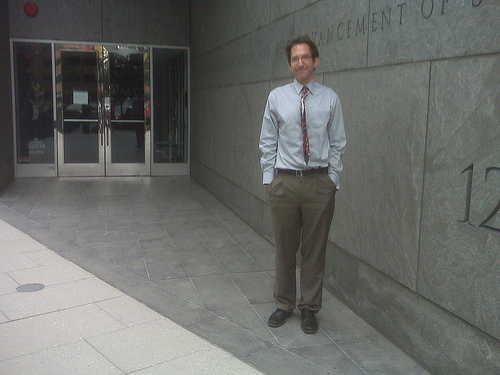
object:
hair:
[285, 34, 319, 67]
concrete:
[1, 174, 433, 375]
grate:
[16, 283, 45, 293]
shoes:
[267, 307, 294, 328]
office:
[9, 38, 190, 183]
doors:
[11, 40, 56, 179]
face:
[290, 43, 315, 81]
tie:
[300, 86, 310, 164]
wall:
[193, 0, 500, 375]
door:
[50, 40, 151, 177]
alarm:
[24, 1, 38, 16]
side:
[2, 3, 192, 175]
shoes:
[300, 310, 319, 335]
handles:
[98, 106, 105, 145]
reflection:
[144, 95, 152, 131]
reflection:
[131, 89, 145, 148]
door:
[149, 43, 190, 177]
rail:
[63, 117, 100, 124]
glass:
[62, 51, 98, 121]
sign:
[73, 91, 89, 105]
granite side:
[192, 0, 499, 375]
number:
[457, 162, 500, 234]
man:
[257, 34, 348, 333]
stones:
[190, 74, 314, 207]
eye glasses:
[289, 55, 313, 61]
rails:
[110, 119, 146, 124]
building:
[0, 0, 500, 375]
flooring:
[0, 175, 440, 375]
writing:
[337, 22, 344, 40]